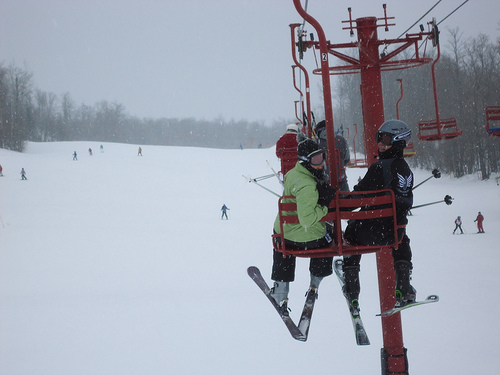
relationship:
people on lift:
[229, 116, 421, 251] [229, 187, 430, 282]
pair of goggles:
[352, 108, 409, 156] [369, 126, 407, 145]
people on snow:
[229, 116, 421, 251] [111, 191, 215, 243]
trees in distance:
[15, 82, 267, 141] [35, 66, 277, 171]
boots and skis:
[312, 230, 455, 314] [317, 290, 441, 366]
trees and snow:
[15, 82, 267, 141] [111, 191, 215, 243]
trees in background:
[15, 82, 267, 141] [35, 66, 277, 171]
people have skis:
[229, 116, 421, 251] [317, 290, 441, 366]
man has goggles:
[319, 103, 441, 354] [369, 126, 407, 145]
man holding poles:
[319, 103, 441, 354] [422, 165, 467, 205]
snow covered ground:
[111, 191, 215, 243] [16, 203, 223, 302]